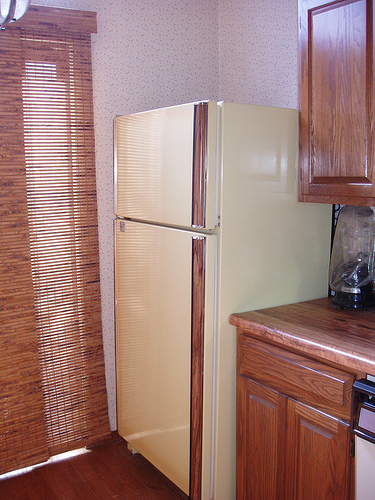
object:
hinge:
[347, 435, 355, 458]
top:
[351, 377, 375, 398]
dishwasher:
[347, 379, 375, 500]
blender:
[328, 204, 375, 313]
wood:
[188, 238, 207, 496]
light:
[0, 448, 95, 483]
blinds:
[0, 5, 112, 473]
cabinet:
[228, 296, 375, 500]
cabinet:
[295, 1, 375, 208]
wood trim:
[190, 104, 209, 228]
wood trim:
[189, 236, 204, 500]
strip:
[208, 102, 221, 500]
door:
[283, 396, 349, 500]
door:
[235, 377, 283, 500]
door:
[111, 100, 208, 235]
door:
[112, 215, 205, 500]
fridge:
[111, 99, 335, 500]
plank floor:
[0, 428, 189, 500]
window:
[0, 26, 79, 479]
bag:
[328, 204, 375, 294]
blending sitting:
[329, 204, 375, 311]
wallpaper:
[29, 0, 296, 434]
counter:
[226, 292, 375, 381]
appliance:
[327, 203, 375, 312]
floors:
[0, 431, 188, 500]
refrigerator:
[75, 117, 234, 287]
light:
[1, 0, 29, 26]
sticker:
[119, 221, 126, 232]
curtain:
[0, 0, 112, 479]